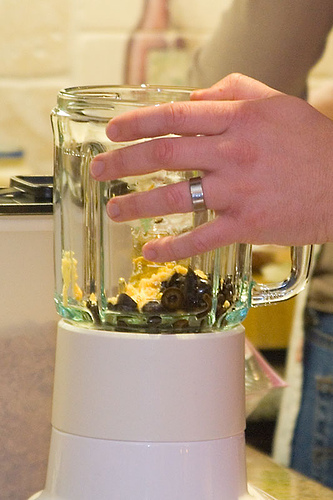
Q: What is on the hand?
A: A silver ring.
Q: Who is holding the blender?
A: A person with jeans on.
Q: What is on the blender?
A: A hand with a ring on it.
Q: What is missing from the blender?
A: A cover.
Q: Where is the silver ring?
A: On the hand holding the blender.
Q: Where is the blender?
A: On a counter.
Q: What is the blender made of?
A: Clear glass.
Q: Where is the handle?
A: Facing the person with jeans.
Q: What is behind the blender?
A: A ziplock bag.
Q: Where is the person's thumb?
A: On top of the blender.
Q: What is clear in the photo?
A: A blender.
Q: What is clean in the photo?
A: The blender.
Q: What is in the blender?
A: Food to be mixed.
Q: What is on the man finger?
A: Ring.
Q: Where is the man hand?
A: On a blender.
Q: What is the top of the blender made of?
A: Glass.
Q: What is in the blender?
A: Olives.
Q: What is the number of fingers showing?
A: Five.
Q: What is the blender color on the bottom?
A: White.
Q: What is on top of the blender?
A: Glass container.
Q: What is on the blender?
A: A hand.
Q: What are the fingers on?
A: Blender.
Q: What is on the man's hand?
A: Wedding band.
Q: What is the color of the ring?
A: Silver.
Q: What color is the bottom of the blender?
A: White.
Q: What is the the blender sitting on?
A: A table.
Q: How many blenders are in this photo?
A: Just one.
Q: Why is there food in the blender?
A: It is being blended.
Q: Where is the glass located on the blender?
A: At the top.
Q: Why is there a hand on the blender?
A: To hold it steady.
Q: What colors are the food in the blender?
A: Yellow and black.